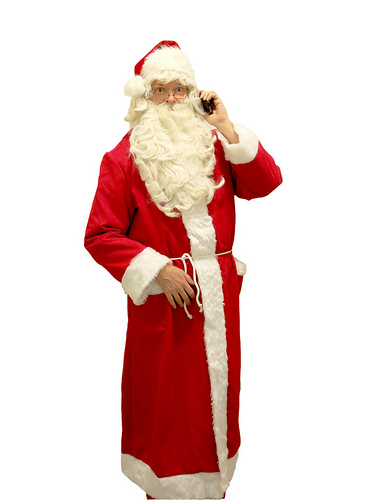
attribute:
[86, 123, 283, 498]
robe — red, white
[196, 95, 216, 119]
cellphone — dark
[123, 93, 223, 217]
beard — long, thick, white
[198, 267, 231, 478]
faux fur — white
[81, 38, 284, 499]
santa — talking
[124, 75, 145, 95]
ball — furry, white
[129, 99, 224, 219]
white beard — long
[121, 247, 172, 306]
fur trim — fake, white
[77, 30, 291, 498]
man — light skinned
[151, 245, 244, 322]
rope — thick, white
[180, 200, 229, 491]
trim — white, faux fur